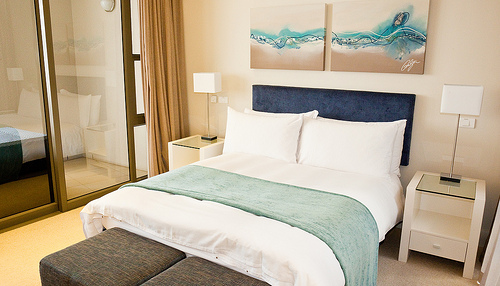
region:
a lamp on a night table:
[190, 70, 220, 145]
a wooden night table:
[396, 169, 485, 279]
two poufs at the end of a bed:
[38, 225, 278, 284]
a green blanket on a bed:
[122, 165, 381, 282]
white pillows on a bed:
[224, 106, 409, 173]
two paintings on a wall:
[246, 3, 430, 73]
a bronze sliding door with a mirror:
[1, 1, 138, 227]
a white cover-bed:
[80, 150, 404, 282]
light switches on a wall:
[208, 93, 228, 104]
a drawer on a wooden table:
[408, 230, 468, 262]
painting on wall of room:
[236, 1, 445, 78]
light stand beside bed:
[393, 163, 485, 284]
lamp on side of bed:
[183, 60, 228, 143]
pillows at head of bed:
[222, 102, 408, 175]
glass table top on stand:
[417, 170, 478, 203]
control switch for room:
[460, 115, 477, 135]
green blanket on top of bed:
[145, 171, 378, 235]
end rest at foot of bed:
[39, 232, 169, 284]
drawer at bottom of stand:
[405, 223, 469, 265]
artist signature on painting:
[395, 52, 427, 75]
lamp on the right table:
[439, 83, 484, 183]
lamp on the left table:
[193, 71, 222, 141]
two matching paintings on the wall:
[248, 0, 430, 75]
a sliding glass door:
[0, 0, 60, 230]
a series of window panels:
[0, 0, 150, 229]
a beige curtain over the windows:
[135, 0, 186, 178]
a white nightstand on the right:
[397, 170, 485, 278]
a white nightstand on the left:
[167, 133, 225, 171]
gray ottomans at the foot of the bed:
[39, 226, 271, 284]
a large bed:
[80, 83, 418, 284]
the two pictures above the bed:
[250, 2, 430, 74]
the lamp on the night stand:
[438, 83, 484, 183]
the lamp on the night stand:
[193, 70, 221, 139]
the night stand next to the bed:
[396, 168, 486, 280]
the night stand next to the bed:
[168, 133, 225, 173]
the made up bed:
[83, 79, 415, 284]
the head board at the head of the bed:
[252, 83, 417, 172]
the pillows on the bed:
[222, 106, 406, 177]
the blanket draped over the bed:
[118, 165, 379, 283]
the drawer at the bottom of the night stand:
[408, 231, 467, 262]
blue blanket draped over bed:
[137, 157, 370, 270]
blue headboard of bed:
[244, 82, 416, 157]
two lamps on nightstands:
[188, 69, 483, 186]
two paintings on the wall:
[245, 2, 421, 68]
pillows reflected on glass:
[13, 80, 97, 134]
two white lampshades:
[190, 65, 482, 115]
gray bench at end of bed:
[51, 223, 234, 285]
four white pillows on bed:
[229, 105, 403, 166]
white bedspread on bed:
[118, 149, 385, 271]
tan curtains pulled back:
[135, 1, 192, 168]